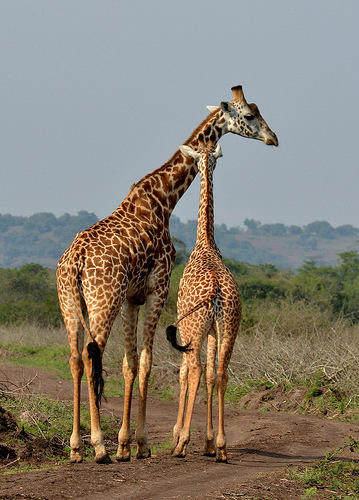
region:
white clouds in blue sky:
[7, 70, 69, 143]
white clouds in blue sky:
[12, 123, 52, 211]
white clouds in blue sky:
[61, 127, 116, 197]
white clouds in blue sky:
[61, 11, 137, 131]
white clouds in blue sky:
[124, 12, 185, 93]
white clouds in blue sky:
[196, 12, 286, 80]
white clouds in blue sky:
[263, 21, 324, 101]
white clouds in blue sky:
[228, 152, 323, 208]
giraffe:
[183, 140, 245, 462]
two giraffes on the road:
[45, 80, 278, 460]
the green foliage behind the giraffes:
[258, 257, 344, 299]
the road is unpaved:
[11, 375, 333, 498]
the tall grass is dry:
[250, 323, 346, 379]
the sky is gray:
[20, 11, 148, 100]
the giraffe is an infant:
[166, 136, 240, 471]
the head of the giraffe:
[206, 82, 295, 149]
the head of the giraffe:
[168, 135, 230, 174]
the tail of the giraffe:
[59, 265, 121, 381]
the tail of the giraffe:
[160, 284, 217, 360]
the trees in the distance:
[1, 209, 356, 270]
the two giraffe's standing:
[54, 84, 277, 464]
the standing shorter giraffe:
[166, 141, 241, 462]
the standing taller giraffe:
[55, 84, 277, 464]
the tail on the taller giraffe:
[65, 257, 107, 407]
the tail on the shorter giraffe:
[164, 281, 215, 353]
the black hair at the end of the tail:
[165, 324, 193, 353]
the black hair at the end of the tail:
[86, 341, 107, 408]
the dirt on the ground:
[2, 345, 356, 496]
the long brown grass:
[1, 307, 357, 393]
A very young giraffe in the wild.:
[164, 139, 240, 463]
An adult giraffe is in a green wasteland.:
[54, 85, 277, 462]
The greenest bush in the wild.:
[0, 236, 357, 327]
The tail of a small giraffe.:
[164, 286, 219, 353]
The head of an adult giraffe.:
[204, 83, 278, 147]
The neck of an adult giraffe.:
[109, 109, 224, 217]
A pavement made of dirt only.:
[0, 359, 356, 496]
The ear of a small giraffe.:
[177, 143, 197, 158]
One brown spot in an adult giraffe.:
[134, 204, 151, 225]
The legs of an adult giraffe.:
[59, 303, 164, 463]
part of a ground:
[242, 447, 255, 465]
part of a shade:
[244, 420, 268, 479]